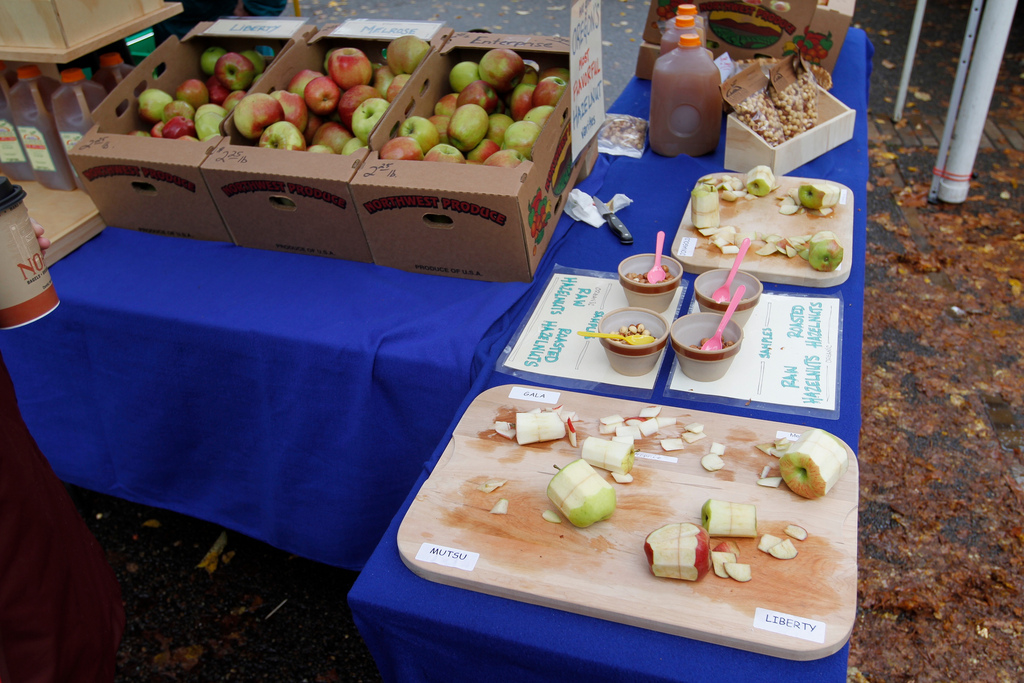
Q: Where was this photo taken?
A: At a fair.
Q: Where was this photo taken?
A: At a market.